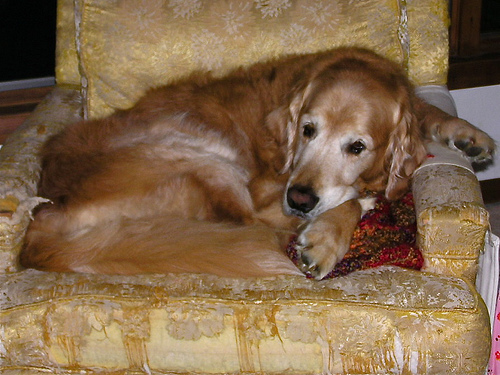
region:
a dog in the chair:
[14, 53, 444, 318]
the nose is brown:
[277, 177, 316, 218]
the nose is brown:
[274, 165, 330, 230]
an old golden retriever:
[13, 13, 490, 325]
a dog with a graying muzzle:
[285, 87, 402, 217]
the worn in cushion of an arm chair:
[47, 250, 470, 369]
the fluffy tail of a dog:
[90, 216, 308, 286]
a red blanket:
[363, 212, 422, 276]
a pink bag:
[488, 310, 499, 336]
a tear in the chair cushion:
[370, 335, 427, 373]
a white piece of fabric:
[417, 86, 478, 178]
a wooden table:
[6, 80, 35, 124]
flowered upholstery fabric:
[176, 25, 251, 82]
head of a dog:
[256, 82, 419, 227]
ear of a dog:
[256, 87, 318, 174]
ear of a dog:
[380, 110, 422, 201]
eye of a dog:
[297, 105, 333, 135]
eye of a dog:
[337, 130, 384, 162]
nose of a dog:
[285, 177, 330, 217]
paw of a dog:
[280, 239, 358, 272]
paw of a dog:
[435, 120, 491, 162]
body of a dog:
[3, 40, 291, 275]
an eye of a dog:
[288, 116, 344, 144]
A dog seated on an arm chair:
[13, 8, 498, 320]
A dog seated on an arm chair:
[13, 39, 498, 299]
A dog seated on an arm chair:
[15, 39, 498, 291]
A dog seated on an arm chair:
[7, 45, 496, 287]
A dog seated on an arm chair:
[12, 41, 498, 295]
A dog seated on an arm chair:
[15, 33, 498, 302]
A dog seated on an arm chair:
[10, 40, 497, 307]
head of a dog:
[271, 76, 416, 224]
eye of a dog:
[283, 105, 330, 137]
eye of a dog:
[336, 130, 388, 167]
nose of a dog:
[279, 187, 325, 209]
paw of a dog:
[283, 232, 357, 289]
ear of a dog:
[362, 88, 436, 209]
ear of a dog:
[263, 81, 323, 192]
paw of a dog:
[436, 114, 497, 173]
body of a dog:
[16, 58, 331, 282]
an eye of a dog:
[288, 119, 339, 141]